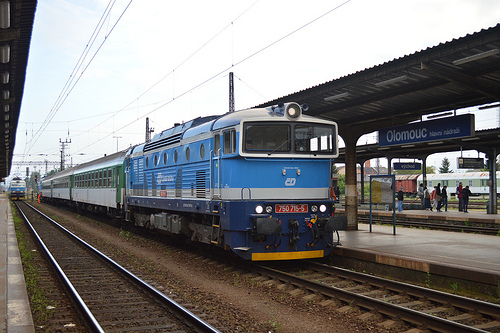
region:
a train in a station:
[42, 93, 345, 278]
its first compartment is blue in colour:
[111, 108, 352, 283]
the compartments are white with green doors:
[42, 148, 115, 206]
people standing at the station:
[404, 165, 486, 212]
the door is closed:
[203, 133, 223, 194]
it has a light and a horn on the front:
[273, 102, 315, 119]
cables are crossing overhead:
[43, 0, 309, 59]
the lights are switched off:
[329, 49, 470, 97]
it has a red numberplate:
[268, 200, 310, 217]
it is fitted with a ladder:
[208, 151, 223, 248]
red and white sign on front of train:
[277, 202, 307, 214]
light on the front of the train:
[282, 101, 302, 118]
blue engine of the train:
[128, 93, 343, 268]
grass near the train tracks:
[17, 259, 55, 319]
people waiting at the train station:
[412, 175, 484, 217]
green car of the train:
[71, 145, 130, 218]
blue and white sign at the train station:
[382, 112, 482, 151]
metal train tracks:
[49, 247, 158, 318]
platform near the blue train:
[349, 237, 441, 290]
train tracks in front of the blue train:
[289, 278, 418, 330]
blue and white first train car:
[119, 97, 344, 260]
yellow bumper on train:
[245, 244, 330, 259]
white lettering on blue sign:
[377, 110, 472, 148]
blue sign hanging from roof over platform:
[368, 108, 478, 143]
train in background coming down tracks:
[3, 177, 221, 332]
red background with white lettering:
[267, 200, 312, 214]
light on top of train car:
[277, 100, 303, 120]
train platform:
[327, 196, 498, 295]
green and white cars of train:
[34, 157, 121, 210]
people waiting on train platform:
[410, 178, 470, 205]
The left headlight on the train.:
[253, 206, 275, 212]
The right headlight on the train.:
[315, 204, 329, 212]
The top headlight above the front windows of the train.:
[286, 100, 300, 117]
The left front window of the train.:
[245, 120, 290, 153]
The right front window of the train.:
[297, 126, 338, 151]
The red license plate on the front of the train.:
[277, 203, 309, 213]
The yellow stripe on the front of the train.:
[251, 246, 326, 262]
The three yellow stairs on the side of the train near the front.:
[210, 198, 220, 243]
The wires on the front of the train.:
[260, 217, 327, 252]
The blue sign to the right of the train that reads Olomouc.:
[372, 112, 481, 153]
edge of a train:
[218, 171, 253, 238]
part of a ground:
[173, 255, 201, 294]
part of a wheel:
[191, 200, 219, 242]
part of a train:
[203, 228, 230, 269]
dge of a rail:
[326, 255, 358, 294]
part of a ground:
[180, 260, 209, 304]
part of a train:
[252, 185, 292, 249]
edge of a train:
[224, 139, 247, 184]